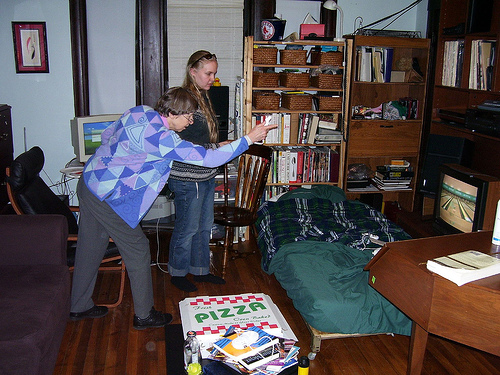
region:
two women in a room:
[78, 14, 456, 361]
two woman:
[49, 21, 494, 327]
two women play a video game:
[60, 36, 499, 348]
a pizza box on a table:
[175, 275, 288, 372]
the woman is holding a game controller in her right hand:
[95, 37, 327, 324]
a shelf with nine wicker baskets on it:
[241, 12, 359, 222]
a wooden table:
[365, 210, 496, 361]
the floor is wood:
[35, 164, 497, 373]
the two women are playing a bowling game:
[80, 34, 480, 321]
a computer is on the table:
[60, 97, 213, 202]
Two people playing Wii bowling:
[54, 46, 499, 331]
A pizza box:
[155, 285, 312, 370]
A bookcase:
[217, 15, 437, 230]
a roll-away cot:
[245, 172, 420, 357]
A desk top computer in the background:
[35, 86, 180, 231]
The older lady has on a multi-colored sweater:
[60, 75, 287, 320]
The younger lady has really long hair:
[150, 36, 265, 291]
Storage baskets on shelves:
[225, 26, 365, 111]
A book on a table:
[345, 210, 495, 345]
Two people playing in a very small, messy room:
[6, 17, 496, 337]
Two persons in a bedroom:
[62, 47, 290, 344]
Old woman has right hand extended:
[63, 84, 287, 339]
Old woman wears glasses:
[66, 83, 284, 331]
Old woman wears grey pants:
[56, 77, 293, 334]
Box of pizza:
[171, 285, 296, 355]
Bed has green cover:
[245, 168, 440, 363]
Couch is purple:
[0, 207, 84, 372]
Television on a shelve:
[410, 153, 491, 244]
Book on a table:
[414, 231, 498, 290]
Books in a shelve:
[236, 99, 348, 199]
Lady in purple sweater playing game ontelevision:
[65, 86, 282, 327]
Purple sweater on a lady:
[81, 105, 251, 230]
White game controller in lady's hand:
[259, 113, 278, 133]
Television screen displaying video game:
[438, 172, 476, 236]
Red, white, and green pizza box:
[177, 288, 298, 351]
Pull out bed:
[259, 187, 409, 362]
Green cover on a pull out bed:
[268, 240, 410, 338]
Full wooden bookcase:
[243, 37, 349, 200]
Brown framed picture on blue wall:
[10, 21, 50, 77]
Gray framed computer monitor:
[68, 113, 127, 160]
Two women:
[72, 41, 292, 290]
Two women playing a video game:
[41, 50, 484, 268]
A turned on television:
[428, 155, 491, 258]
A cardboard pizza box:
[144, 284, 308, 367]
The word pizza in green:
[181, 292, 275, 331]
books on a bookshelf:
[250, 97, 345, 198]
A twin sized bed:
[255, 179, 405, 347]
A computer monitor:
[60, 98, 136, 180]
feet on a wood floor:
[68, 266, 177, 367]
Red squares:
[182, 290, 273, 313]